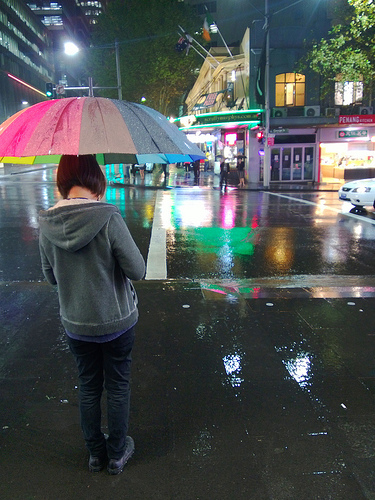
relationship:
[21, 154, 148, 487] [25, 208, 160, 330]
girl wearing jacket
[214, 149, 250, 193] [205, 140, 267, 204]
people at sidewalk